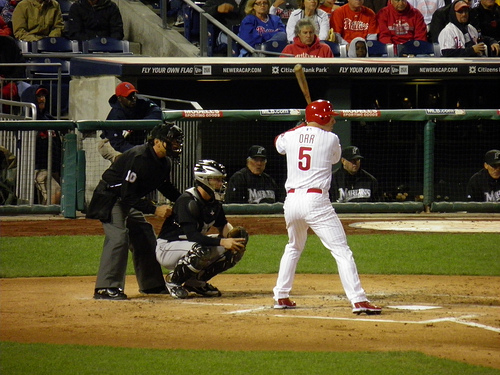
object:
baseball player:
[271, 98, 381, 332]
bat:
[291, 61, 313, 100]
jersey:
[274, 125, 342, 195]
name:
[298, 132, 316, 144]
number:
[297, 146, 314, 173]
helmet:
[301, 99, 339, 126]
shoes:
[268, 293, 382, 318]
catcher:
[154, 159, 249, 298]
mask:
[204, 173, 235, 199]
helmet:
[193, 157, 229, 202]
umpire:
[85, 115, 186, 300]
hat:
[113, 81, 139, 99]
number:
[124, 168, 140, 183]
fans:
[208, 1, 498, 54]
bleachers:
[2, 0, 499, 74]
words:
[135, 65, 220, 78]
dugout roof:
[70, 51, 498, 80]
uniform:
[271, 126, 362, 302]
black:
[166, 194, 204, 236]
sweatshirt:
[107, 103, 155, 143]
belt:
[283, 186, 335, 194]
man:
[96, 79, 164, 166]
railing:
[349, 102, 498, 221]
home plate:
[384, 301, 446, 314]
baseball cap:
[245, 143, 271, 159]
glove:
[225, 226, 249, 258]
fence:
[3, 97, 41, 204]